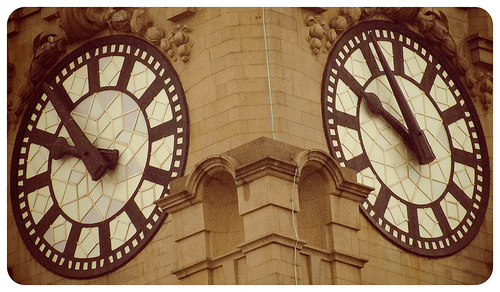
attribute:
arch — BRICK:
[181, 151, 243, 201]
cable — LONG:
[260, 8, 277, 140]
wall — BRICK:
[8, 7, 493, 284]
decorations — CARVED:
[134, 5, 201, 69]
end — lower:
[98, 146, 123, 174]